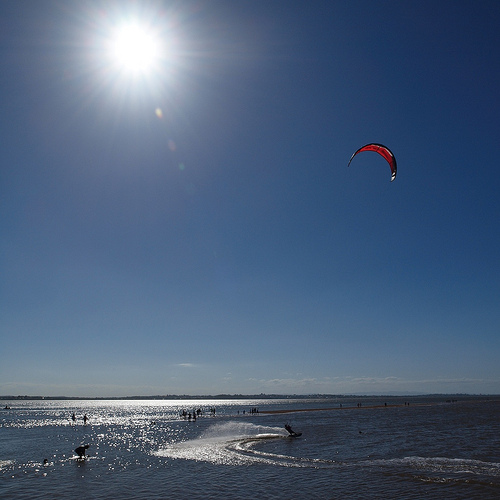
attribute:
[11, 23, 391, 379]
sky — blue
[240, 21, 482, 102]
sky — blue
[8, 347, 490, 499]
beach — beautiful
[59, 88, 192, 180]
sky — beach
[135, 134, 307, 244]
clouds — white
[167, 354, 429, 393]
cloud — white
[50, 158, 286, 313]
sky — blue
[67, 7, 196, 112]
sun — bright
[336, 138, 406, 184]
kite — red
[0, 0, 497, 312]
sky — blue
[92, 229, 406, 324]
sky — blue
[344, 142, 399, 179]
kite — red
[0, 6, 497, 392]
sky — blue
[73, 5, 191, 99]
sun — bright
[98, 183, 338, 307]
sky — blue